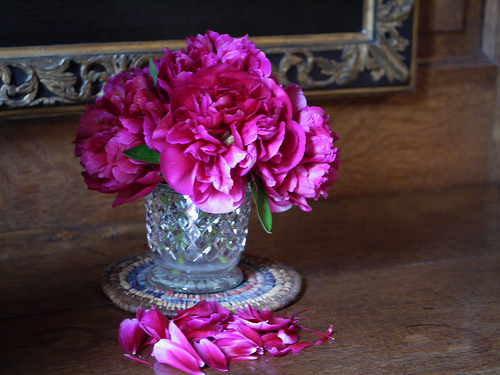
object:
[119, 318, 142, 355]
petal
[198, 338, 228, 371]
petal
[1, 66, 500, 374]
table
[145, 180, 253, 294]
vase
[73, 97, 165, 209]
flower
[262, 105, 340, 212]
flower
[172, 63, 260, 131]
flower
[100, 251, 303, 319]
coaster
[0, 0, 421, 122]
frame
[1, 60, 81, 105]
pattern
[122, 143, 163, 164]
leaf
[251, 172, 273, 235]
leaf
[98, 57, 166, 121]
flower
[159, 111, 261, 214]
flowers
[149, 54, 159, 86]
leaf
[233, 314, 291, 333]
petal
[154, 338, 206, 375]
petal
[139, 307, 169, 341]
petal